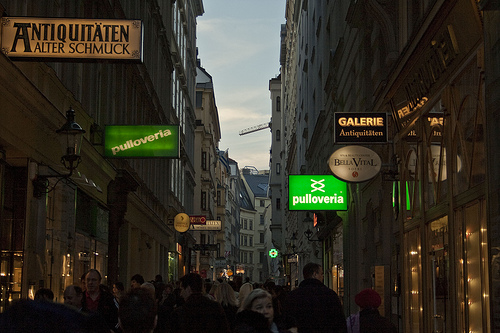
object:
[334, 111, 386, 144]
black sign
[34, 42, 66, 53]
word alter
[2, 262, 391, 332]
crowd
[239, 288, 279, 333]
person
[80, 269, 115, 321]
person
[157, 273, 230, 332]
person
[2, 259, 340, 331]
street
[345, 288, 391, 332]
woman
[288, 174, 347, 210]
store sign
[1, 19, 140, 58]
sign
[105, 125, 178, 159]
sign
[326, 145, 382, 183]
sign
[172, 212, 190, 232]
sign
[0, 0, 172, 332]
building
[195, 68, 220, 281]
building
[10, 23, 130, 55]
writing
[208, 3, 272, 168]
sunlight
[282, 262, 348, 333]
people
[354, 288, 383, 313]
head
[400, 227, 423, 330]
window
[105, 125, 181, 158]
green sign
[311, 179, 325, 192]
logo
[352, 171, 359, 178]
logo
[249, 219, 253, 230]
windows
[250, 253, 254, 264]
windows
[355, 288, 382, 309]
cap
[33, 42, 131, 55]
writing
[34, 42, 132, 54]
alter schmuck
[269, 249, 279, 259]
green lights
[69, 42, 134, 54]
word schmuck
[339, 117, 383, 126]
lettering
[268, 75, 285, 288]
buildings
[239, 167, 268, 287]
buildings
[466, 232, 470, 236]
lights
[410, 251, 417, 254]
lights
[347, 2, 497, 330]
building